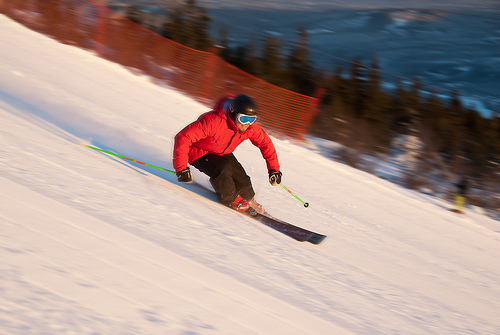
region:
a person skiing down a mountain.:
[66, 94, 344, 240]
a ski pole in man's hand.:
[269, 181, 324, 216]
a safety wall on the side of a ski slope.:
[0, 1, 315, 144]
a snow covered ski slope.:
[3, 16, 498, 330]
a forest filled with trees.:
[0, 6, 498, 217]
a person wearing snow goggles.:
[218, 93, 258, 128]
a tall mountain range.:
[176, 0, 497, 135]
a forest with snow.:
[311, 80, 489, 221]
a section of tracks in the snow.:
[46, 202, 337, 322]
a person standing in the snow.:
[433, 161, 477, 218]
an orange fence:
[2, 0, 334, 147]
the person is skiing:
[83, 75, 360, 254]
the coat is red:
[141, 72, 309, 198]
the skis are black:
[168, 152, 336, 257]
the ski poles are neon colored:
[56, 112, 329, 247]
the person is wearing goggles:
[221, 88, 265, 141]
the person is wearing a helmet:
[206, 74, 274, 146]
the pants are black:
[175, 136, 273, 221]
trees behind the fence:
[111, 1, 498, 205]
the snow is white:
[18, 40, 432, 321]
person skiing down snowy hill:
[140, 79, 321, 270]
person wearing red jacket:
[205, 122, 265, 153]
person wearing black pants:
[202, 162, 250, 197]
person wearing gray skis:
[265, 210, 327, 257]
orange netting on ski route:
[58, 14, 216, 112]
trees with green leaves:
[330, 79, 495, 171]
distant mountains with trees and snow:
[326, 7, 483, 58]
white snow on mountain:
[364, 210, 481, 323]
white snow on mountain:
[119, 232, 281, 319]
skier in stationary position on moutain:
[448, 170, 474, 215]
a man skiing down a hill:
[86, 81, 324, 246]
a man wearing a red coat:
[172, 96, 282, 221]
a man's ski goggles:
[236, 111, 257, 125]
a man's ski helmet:
[227, 93, 257, 114]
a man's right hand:
[177, 166, 193, 182]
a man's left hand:
[266, 169, 284, 184]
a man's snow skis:
[98, 138, 325, 245]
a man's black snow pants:
[191, 148, 258, 198]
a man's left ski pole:
[277, 179, 309, 211]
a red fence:
[0, 1, 320, 142]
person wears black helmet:
[220, 91, 257, 121]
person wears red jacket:
[158, 109, 283, 174]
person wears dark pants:
[178, 142, 261, 201]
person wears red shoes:
[213, 194, 264, 224]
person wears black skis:
[199, 166, 316, 248]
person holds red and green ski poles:
[128, 148, 308, 216]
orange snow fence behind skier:
[13, 1, 335, 159]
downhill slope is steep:
[10, 39, 465, 334]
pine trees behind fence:
[91, 0, 489, 200]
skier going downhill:
[131, 82, 323, 249]